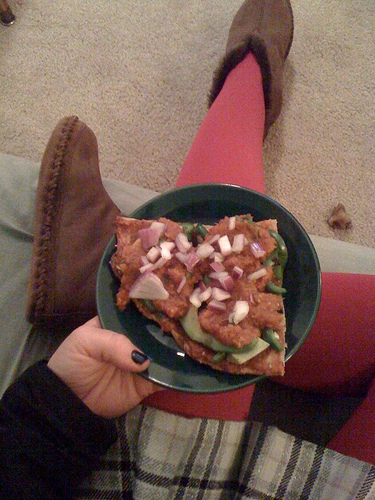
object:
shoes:
[206, 3, 293, 129]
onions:
[129, 265, 169, 305]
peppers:
[186, 220, 213, 245]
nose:
[326, 201, 353, 232]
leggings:
[175, 44, 265, 195]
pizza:
[100, 208, 295, 393]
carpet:
[0, 1, 372, 242]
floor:
[1, 3, 375, 243]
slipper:
[26, 112, 133, 333]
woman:
[0, 0, 375, 495]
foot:
[26, 115, 127, 329]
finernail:
[129, 345, 151, 370]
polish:
[129, 345, 154, 369]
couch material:
[65, 387, 370, 498]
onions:
[210, 242, 232, 258]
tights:
[174, 49, 264, 190]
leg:
[266, 272, 373, 386]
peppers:
[264, 226, 288, 299]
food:
[100, 197, 291, 386]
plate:
[95, 180, 324, 400]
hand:
[49, 315, 172, 416]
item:
[327, 200, 355, 231]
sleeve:
[0, 363, 107, 496]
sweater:
[0, 328, 121, 497]